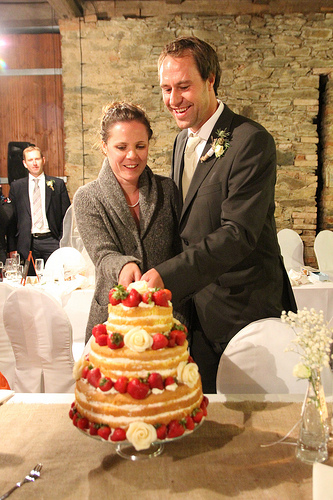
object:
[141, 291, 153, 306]
strawberry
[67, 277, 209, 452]
cake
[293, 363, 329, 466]
vase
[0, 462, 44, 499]
fork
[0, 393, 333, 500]
table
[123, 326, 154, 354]
rose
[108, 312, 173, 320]
filling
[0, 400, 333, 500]
table runner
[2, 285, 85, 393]
chair cover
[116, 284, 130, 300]
stem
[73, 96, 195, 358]
woman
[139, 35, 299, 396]
man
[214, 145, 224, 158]
flower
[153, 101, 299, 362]
coat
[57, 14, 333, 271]
stone wall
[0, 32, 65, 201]
wood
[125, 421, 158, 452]
rose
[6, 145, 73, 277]
man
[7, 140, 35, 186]
speaker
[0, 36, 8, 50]
light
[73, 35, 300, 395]
couple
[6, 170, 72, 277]
suit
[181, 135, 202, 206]
tie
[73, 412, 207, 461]
stand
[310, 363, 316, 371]
flowers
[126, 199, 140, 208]
necklace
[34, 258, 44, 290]
glass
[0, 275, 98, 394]
table